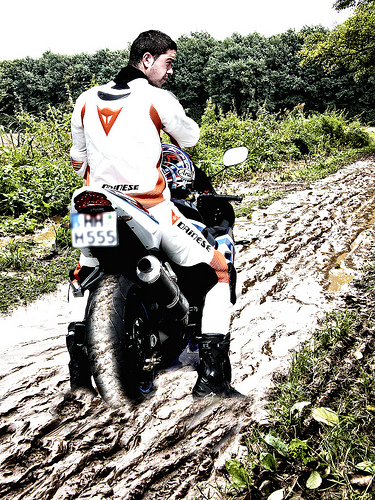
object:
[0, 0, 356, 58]
sky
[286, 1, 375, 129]
trees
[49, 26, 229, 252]
man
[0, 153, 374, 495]
road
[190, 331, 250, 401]
shoe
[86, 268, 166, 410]
wheel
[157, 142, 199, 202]
helmet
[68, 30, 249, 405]
cyclist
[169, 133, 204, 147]
handle bar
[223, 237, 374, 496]
road side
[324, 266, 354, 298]
water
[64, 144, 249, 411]
motorbike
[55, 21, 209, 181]
man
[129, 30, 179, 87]
head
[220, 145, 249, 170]
mirror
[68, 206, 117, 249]
registration number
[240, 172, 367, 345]
road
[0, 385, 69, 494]
ground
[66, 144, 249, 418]
bike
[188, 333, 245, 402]
boots